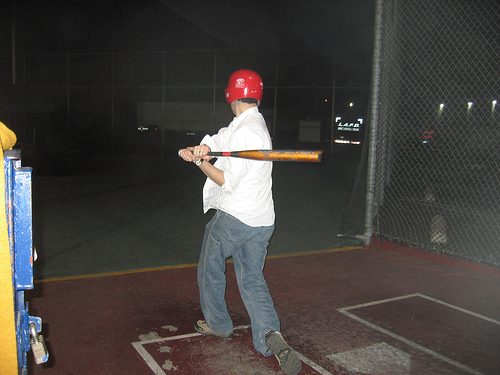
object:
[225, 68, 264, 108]
helmet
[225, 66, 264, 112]
head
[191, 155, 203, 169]
watch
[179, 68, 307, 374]
man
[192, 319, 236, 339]
shoes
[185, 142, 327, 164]
bat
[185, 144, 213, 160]
hands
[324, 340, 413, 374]
base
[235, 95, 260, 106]
hair